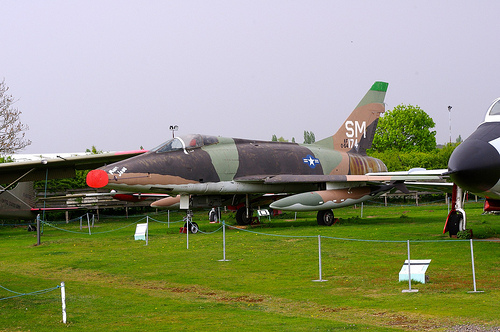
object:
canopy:
[150, 132, 210, 155]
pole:
[31, 209, 46, 244]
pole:
[467, 235, 479, 294]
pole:
[83, 211, 95, 235]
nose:
[438, 144, 497, 196]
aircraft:
[442, 96, 500, 237]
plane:
[84, 76, 449, 233]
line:
[221, 221, 500, 247]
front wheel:
[183, 220, 201, 235]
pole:
[57, 282, 72, 326]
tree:
[367, 102, 435, 154]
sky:
[0, 0, 500, 147]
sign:
[133, 224, 148, 243]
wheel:
[443, 210, 463, 239]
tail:
[314, 81, 388, 149]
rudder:
[324, 79, 396, 153]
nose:
[81, 169, 109, 191]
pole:
[358, 202, 367, 219]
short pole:
[306, 231, 331, 283]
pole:
[181, 219, 192, 247]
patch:
[238, 272, 267, 284]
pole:
[217, 217, 231, 260]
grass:
[0, 199, 500, 331]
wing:
[238, 168, 447, 187]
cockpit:
[152, 131, 208, 159]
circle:
[303, 156, 318, 169]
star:
[305, 154, 315, 164]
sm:
[345, 118, 370, 138]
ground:
[0, 196, 500, 331]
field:
[0, 195, 500, 331]